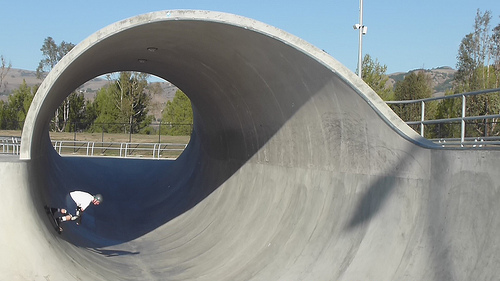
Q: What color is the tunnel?
A: Gray.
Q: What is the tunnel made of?
A: Cement.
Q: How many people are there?
A: One.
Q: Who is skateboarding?
A: The man.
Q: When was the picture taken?
A: Daytime.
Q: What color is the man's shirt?
A: White.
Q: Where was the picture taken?
A: At a skatepark.